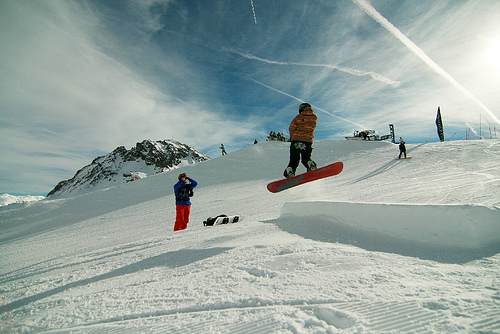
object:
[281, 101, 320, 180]
person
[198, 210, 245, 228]
snowboard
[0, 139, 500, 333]
snow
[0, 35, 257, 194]
clouds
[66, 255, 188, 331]
tracks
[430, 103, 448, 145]
flag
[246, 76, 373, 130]
lines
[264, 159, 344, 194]
snowboard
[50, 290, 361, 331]
lines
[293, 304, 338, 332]
print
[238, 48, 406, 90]
streaks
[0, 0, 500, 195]
sky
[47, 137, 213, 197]
snow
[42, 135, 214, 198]
mountain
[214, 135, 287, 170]
hill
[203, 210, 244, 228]
bag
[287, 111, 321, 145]
jacket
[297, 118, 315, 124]
lines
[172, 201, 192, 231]
pants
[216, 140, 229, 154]
skier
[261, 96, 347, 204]
skier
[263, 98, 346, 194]
snowboarder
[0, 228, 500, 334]
ground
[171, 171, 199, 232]
people